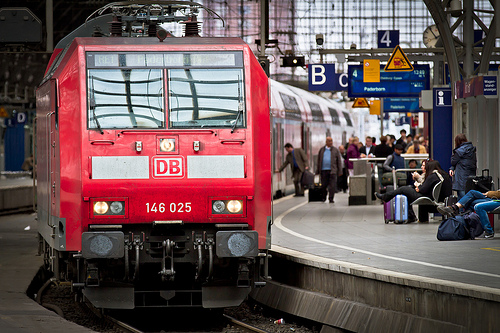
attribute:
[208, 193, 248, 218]
headlight — head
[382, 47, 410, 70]
signs — overhead 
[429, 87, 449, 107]
letter — I